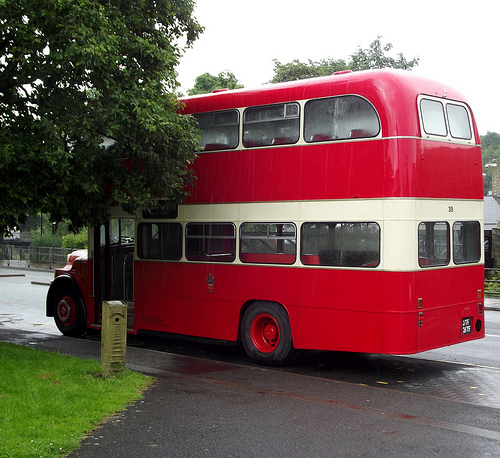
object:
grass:
[3, 336, 153, 455]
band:
[128, 189, 497, 275]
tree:
[4, 0, 209, 254]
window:
[413, 218, 453, 269]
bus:
[44, 66, 489, 367]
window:
[235, 218, 301, 266]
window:
[183, 219, 237, 267]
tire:
[240, 295, 290, 360]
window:
[297, 216, 382, 278]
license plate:
[452, 314, 477, 334]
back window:
[416, 93, 476, 144]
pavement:
[73, 376, 500, 455]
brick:
[356, 363, 413, 390]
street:
[123, 348, 476, 447]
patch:
[0, 342, 82, 405]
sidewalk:
[157, 322, 482, 451]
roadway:
[0, 268, 500, 457]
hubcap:
[250, 313, 279, 353]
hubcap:
[55, 292, 76, 326]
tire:
[45, 287, 81, 336]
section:
[11, 240, 68, 263]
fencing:
[0, 237, 67, 269]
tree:
[10, 14, 255, 283]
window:
[449, 219, 482, 269]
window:
[302, 95, 383, 143]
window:
[239, 220, 299, 262]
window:
[302, 222, 382, 265]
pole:
[100, 297, 132, 380]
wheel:
[44, 280, 90, 335]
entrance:
[87, 202, 137, 328]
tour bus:
[44, 65, 488, 368]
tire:
[237, 298, 294, 368]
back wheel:
[238, 300, 292, 365]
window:
[416, 215, 447, 269]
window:
[141, 220, 183, 258]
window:
[242, 102, 302, 147]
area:
[3, 343, 142, 455]